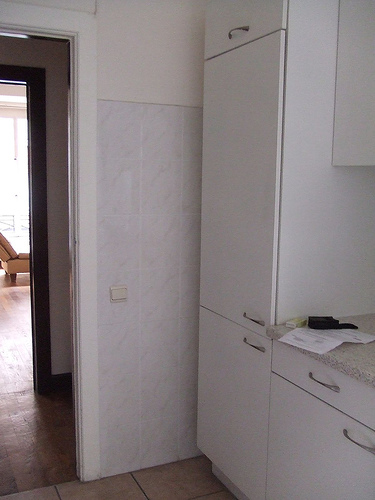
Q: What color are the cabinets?
A: White.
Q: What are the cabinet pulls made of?
A: Metal.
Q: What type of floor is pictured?
A: Tile.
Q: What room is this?
A: A kitchen.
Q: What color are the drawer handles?
A: Silver.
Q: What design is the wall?
A: Tile.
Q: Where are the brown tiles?
A: On the floor.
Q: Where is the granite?
A: On the countertop.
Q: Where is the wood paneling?
A: On the living room floor.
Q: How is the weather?
A: Sunny.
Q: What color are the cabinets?
A: White.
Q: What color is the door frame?
A: White.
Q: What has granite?
A: Kitchen top.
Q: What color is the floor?
A: Brown.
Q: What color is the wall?
A: White.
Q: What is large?
A: The cabinet.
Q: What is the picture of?
A: A storage room.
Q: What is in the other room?
A: A chair.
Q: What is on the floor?
A: Tile.